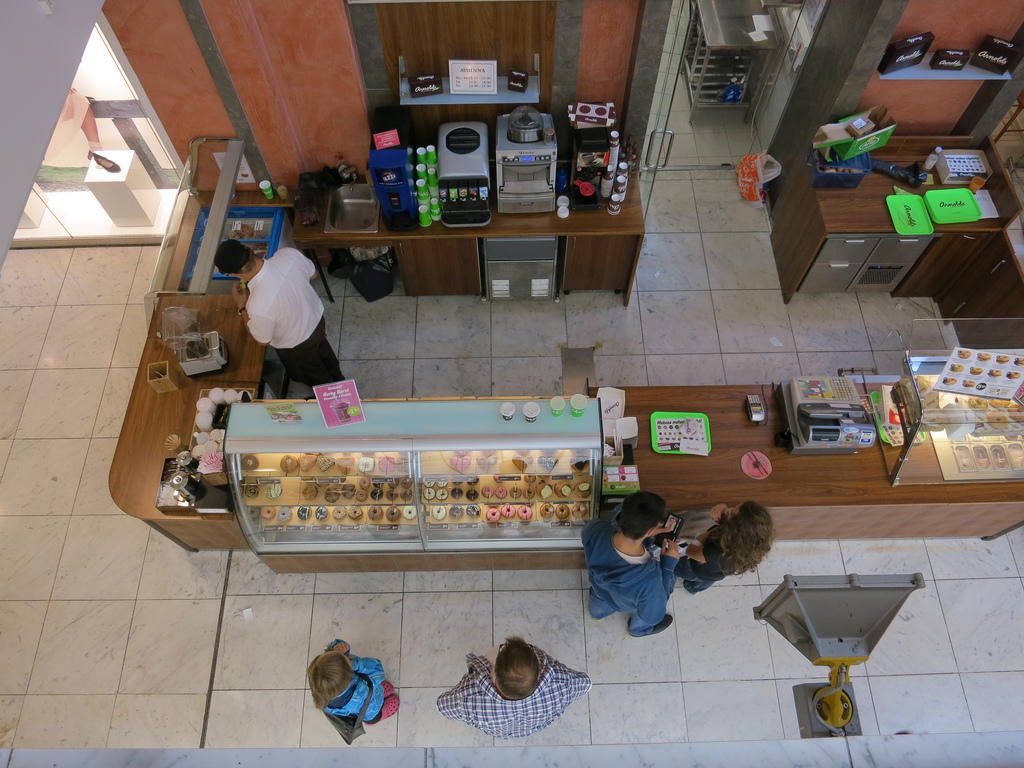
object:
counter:
[588, 383, 1024, 543]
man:
[213, 237, 345, 389]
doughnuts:
[239, 451, 592, 533]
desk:
[766, 134, 1024, 307]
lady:
[673, 501, 772, 597]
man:
[435, 634, 591, 740]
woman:
[307, 639, 402, 745]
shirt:
[321, 638, 387, 723]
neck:
[611, 531, 646, 559]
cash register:
[770, 376, 876, 456]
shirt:
[246, 247, 326, 351]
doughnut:
[402, 505, 416, 520]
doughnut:
[485, 508, 501, 523]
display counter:
[224, 393, 605, 574]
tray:
[884, 193, 933, 236]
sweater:
[578, 518, 680, 626]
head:
[492, 636, 542, 700]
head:
[302, 651, 352, 708]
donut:
[517, 505, 534, 520]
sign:
[312, 378, 367, 430]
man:
[580, 492, 681, 640]